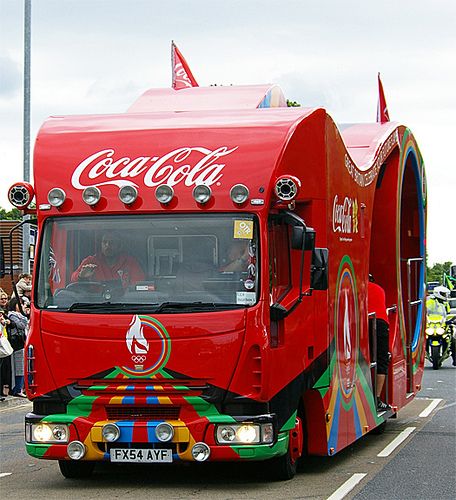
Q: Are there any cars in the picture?
A: No, there are no cars.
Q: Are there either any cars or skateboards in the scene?
A: No, there are no cars or skateboards.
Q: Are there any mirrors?
A: Yes, there is a mirror.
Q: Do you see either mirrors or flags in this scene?
A: Yes, there is a mirror.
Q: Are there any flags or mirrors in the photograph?
A: Yes, there is a mirror.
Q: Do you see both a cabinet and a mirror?
A: No, there is a mirror but no cabinets.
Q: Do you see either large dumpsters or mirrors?
A: Yes, there is a large mirror.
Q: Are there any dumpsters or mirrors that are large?
A: Yes, the mirror is large.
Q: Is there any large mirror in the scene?
A: Yes, there is a large mirror.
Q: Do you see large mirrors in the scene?
A: Yes, there is a large mirror.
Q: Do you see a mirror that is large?
A: Yes, there is a mirror that is large.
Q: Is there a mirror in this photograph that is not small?
A: Yes, there is a large mirror.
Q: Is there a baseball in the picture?
A: No, there are no baseballs.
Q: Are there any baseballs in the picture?
A: No, there are no baseballs.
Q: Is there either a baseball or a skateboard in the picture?
A: No, there are no baseballs or skateboards.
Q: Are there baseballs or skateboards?
A: No, there are no baseballs or skateboards.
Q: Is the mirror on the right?
A: Yes, the mirror is on the right of the image.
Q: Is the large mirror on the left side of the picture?
A: No, the mirror is on the right of the image.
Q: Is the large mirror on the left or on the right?
A: The mirror is on the right of the image.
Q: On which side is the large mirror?
A: The mirror is on the right of the image.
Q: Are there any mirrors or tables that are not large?
A: No, there is a mirror but it is large.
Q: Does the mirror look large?
A: Yes, the mirror is large.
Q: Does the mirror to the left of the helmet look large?
A: Yes, the mirror is large.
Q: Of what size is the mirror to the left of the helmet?
A: The mirror is large.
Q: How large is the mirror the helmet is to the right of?
A: The mirror is large.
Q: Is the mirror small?
A: No, the mirror is large.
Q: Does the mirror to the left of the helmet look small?
A: No, the mirror is large.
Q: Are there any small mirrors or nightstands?
A: No, there is a mirror but it is large.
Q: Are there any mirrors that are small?
A: No, there is a mirror but it is large.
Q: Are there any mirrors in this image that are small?
A: No, there is a mirror but it is large.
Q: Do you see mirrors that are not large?
A: No, there is a mirror but it is large.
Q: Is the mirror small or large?
A: The mirror is large.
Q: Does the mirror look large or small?
A: The mirror is large.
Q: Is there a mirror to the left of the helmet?
A: Yes, there is a mirror to the left of the helmet.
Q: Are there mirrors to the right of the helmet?
A: No, the mirror is to the left of the helmet.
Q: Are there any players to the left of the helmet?
A: No, there is a mirror to the left of the helmet.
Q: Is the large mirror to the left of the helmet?
A: Yes, the mirror is to the left of the helmet.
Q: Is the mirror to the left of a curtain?
A: No, the mirror is to the left of the helmet.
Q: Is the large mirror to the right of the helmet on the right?
A: No, the mirror is to the left of the helmet.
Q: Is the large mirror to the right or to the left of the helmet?
A: The mirror is to the left of the helmet.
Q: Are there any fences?
A: No, there are no fences.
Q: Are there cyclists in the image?
A: No, there are no cyclists.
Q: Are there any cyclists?
A: No, there are no cyclists.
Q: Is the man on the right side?
A: Yes, the man is on the right of the image.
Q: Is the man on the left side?
A: No, the man is on the right of the image.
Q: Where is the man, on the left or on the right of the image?
A: The man is on the right of the image.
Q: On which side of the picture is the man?
A: The man is on the right of the image.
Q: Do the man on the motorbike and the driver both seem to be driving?
A: Yes, both the man and the driver are driving.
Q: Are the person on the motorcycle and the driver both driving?
A: Yes, both the man and the driver are driving.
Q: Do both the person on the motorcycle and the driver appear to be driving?
A: Yes, both the man and the driver are driving.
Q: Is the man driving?
A: Yes, the man is driving.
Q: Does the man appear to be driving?
A: Yes, the man is driving.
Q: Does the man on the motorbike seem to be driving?
A: Yes, the man is driving.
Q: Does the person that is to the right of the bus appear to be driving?
A: Yes, the man is driving.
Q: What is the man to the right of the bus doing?
A: The man is driving.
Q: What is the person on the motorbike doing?
A: The man is driving.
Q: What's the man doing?
A: The man is driving.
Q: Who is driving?
A: The man is driving.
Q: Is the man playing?
A: No, the man is driving.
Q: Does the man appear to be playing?
A: No, the man is driving.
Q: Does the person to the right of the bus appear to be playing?
A: No, the man is driving.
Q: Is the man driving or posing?
A: The man is driving.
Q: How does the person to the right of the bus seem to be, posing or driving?
A: The man is driving.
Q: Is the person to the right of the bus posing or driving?
A: The man is driving.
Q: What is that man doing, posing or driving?
A: The man is driving.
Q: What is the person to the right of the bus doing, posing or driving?
A: The man is driving.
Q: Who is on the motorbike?
A: The man is on the motorbike.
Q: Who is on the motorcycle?
A: The man is on the motorbike.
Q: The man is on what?
A: The man is on the motorbike.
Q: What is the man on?
A: The man is on the motorbike.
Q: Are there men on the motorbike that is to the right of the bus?
A: Yes, there is a man on the motorcycle.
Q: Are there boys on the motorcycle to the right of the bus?
A: No, there is a man on the motorcycle.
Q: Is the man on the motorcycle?
A: Yes, the man is on the motorcycle.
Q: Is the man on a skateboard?
A: No, the man is on the motorcycle.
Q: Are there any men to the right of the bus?
A: Yes, there is a man to the right of the bus.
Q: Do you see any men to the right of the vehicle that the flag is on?
A: Yes, there is a man to the right of the bus.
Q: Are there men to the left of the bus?
A: No, the man is to the right of the bus.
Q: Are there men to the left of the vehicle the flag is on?
A: No, the man is to the right of the bus.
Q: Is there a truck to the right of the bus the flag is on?
A: No, there is a man to the right of the bus.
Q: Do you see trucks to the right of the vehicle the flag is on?
A: No, there is a man to the right of the bus.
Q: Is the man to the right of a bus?
A: Yes, the man is to the right of a bus.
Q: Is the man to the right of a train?
A: No, the man is to the right of a bus.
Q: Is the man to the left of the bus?
A: No, the man is to the right of the bus.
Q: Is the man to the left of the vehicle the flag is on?
A: No, the man is to the right of the bus.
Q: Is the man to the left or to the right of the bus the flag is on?
A: The man is to the right of the bus.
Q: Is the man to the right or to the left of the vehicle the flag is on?
A: The man is to the right of the bus.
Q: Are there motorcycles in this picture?
A: Yes, there is a motorcycle.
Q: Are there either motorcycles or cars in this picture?
A: Yes, there is a motorcycle.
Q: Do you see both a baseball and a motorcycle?
A: No, there is a motorcycle but no baseballs.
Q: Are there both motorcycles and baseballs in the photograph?
A: No, there is a motorcycle but no baseballs.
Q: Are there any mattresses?
A: No, there are no mattresses.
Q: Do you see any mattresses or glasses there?
A: No, there are no mattresses or glasses.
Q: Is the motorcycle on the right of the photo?
A: Yes, the motorcycle is on the right of the image.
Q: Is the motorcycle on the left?
A: No, the motorcycle is on the right of the image.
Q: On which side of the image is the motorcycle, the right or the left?
A: The motorcycle is on the right of the image.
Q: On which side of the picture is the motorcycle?
A: The motorcycle is on the right of the image.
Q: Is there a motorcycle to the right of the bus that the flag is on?
A: Yes, there is a motorcycle to the right of the bus.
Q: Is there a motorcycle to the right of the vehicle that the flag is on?
A: Yes, there is a motorcycle to the right of the bus.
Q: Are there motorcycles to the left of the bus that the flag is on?
A: No, the motorcycle is to the right of the bus.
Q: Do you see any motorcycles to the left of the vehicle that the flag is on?
A: No, the motorcycle is to the right of the bus.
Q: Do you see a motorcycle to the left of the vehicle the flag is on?
A: No, the motorcycle is to the right of the bus.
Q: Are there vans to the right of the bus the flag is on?
A: No, there is a motorcycle to the right of the bus.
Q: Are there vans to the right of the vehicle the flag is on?
A: No, there is a motorcycle to the right of the bus.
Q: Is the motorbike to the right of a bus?
A: Yes, the motorbike is to the right of a bus.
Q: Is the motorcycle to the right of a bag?
A: No, the motorcycle is to the right of a bus.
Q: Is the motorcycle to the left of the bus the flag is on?
A: No, the motorcycle is to the right of the bus.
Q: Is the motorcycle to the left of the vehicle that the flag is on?
A: No, the motorcycle is to the right of the bus.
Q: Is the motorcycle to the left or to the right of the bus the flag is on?
A: The motorcycle is to the right of the bus.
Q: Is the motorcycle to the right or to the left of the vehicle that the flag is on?
A: The motorcycle is to the right of the bus.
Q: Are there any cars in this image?
A: No, there are no cars.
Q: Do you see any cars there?
A: No, there are no cars.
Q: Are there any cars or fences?
A: No, there are no cars or fences.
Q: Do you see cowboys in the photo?
A: No, there are no cowboys.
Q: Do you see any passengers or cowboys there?
A: No, there are no cowboys or passengers.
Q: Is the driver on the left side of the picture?
A: Yes, the driver is on the left of the image.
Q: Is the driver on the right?
A: No, the driver is on the left of the image.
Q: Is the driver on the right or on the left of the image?
A: The driver is on the left of the image.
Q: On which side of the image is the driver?
A: The driver is on the left of the image.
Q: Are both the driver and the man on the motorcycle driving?
A: Yes, both the driver and the man are driving.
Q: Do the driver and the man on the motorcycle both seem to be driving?
A: Yes, both the driver and the man are driving.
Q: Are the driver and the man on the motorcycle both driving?
A: Yes, both the driver and the man are driving.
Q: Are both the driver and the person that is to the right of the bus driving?
A: Yes, both the driver and the man are driving.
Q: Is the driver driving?
A: Yes, the driver is driving.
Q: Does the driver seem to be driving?
A: Yes, the driver is driving.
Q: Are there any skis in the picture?
A: No, there are no skis.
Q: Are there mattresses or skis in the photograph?
A: No, there are no skis or mattresses.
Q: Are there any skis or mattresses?
A: No, there are no skis or mattresses.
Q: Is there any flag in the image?
A: Yes, there is a flag.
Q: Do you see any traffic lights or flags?
A: Yes, there is a flag.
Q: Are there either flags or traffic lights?
A: Yes, there is a flag.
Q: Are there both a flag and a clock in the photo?
A: No, there is a flag but no clocks.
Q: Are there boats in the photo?
A: No, there are no boats.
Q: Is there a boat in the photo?
A: No, there are no boats.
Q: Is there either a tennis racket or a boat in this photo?
A: No, there are no boats or rackets.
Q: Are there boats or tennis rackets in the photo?
A: No, there are no boats or tennis rackets.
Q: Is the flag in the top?
A: Yes, the flag is in the top of the image.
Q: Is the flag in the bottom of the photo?
A: No, the flag is in the top of the image.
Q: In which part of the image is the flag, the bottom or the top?
A: The flag is in the top of the image.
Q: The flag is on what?
A: The flag is on the bus.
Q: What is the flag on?
A: The flag is on the bus.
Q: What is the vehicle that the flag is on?
A: The vehicle is a bus.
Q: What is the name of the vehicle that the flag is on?
A: The vehicle is a bus.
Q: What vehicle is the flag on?
A: The flag is on the bus.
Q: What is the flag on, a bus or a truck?
A: The flag is on a bus.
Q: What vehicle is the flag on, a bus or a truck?
A: The flag is on a bus.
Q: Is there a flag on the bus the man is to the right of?
A: Yes, there is a flag on the bus.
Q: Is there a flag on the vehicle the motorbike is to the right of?
A: Yes, there is a flag on the bus.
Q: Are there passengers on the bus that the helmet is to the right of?
A: No, there is a flag on the bus.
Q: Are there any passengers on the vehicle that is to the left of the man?
A: No, there is a flag on the bus.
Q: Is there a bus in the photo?
A: Yes, there is a bus.